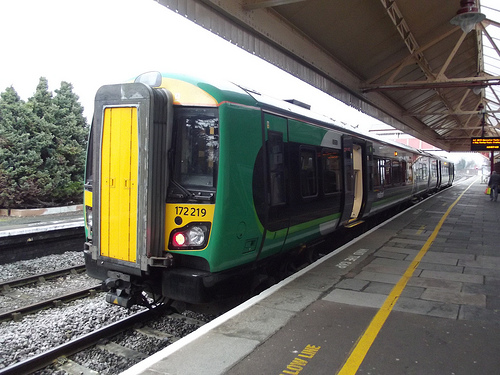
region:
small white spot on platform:
[286, 342, 303, 355]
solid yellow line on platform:
[362, 301, 409, 356]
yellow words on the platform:
[281, 342, 343, 356]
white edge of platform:
[209, 314, 254, 341]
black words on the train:
[164, 201, 241, 222]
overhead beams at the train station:
[389, 31, 499, 128]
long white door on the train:
[347, 136, 380, 233]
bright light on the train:
[163, 221, 230, 260]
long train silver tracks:
[8, 242, 141, 364]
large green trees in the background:
[22, 80, 75, 215]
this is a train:
[94, 86, 255, 234]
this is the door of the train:
[102, 109, 133, 258]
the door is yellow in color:
[112, 113, 128, 245]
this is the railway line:
[56, 340, 101, 372]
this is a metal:
[54, 343, 79, 348]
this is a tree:
[8, 110, 28, 161]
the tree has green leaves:
[3, 107, 30, 167]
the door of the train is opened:
[353, 146, 359, 188]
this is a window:
[301, 152, 313, 189]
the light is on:
[172, 233, 183, 242]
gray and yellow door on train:
[85, 77, 161, 277]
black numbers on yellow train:
[174, 200, 216, 229]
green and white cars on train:
[211, 98, 377, 248]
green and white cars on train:
[360, 132, 437, 214]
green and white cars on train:
[431, 151, 459, 193]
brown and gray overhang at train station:
[216, 8, 477, 74]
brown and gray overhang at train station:
[374, 60, 479, 140]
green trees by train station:
[6, 93, 84, 193]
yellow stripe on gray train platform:
[289, 300, 484, 362]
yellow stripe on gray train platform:
[409, 193, 447, 316]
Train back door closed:
[100, 83, 158, 280]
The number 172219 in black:
[165, 198, 214, 225]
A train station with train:
[109, 63, 499, 305]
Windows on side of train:
[263, 136, 343, 202]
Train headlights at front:
[167, 226, 211, 253]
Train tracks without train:
[13, 253, 80, 326]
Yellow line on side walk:
[376, 211, 423, 338]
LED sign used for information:
[473, 136, 498, 153]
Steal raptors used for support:
[427, 33, 493, 96]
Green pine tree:
[18, 81, 80, 189]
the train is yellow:
[83, 101, 213, 286]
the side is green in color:
[228, 116, 353, 256]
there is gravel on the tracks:
[31, 258, 131, 366]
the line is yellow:
[361, 229, 451, 371]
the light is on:
[147, 227, 224, 261]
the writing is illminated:
[466, 131, 498, 151]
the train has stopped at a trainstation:
[253, 143, 498, 212]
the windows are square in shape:
[283, 146, 331, 209]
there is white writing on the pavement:
[323, 234, 380, 279]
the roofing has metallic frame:
[378, 67, 487, 152]